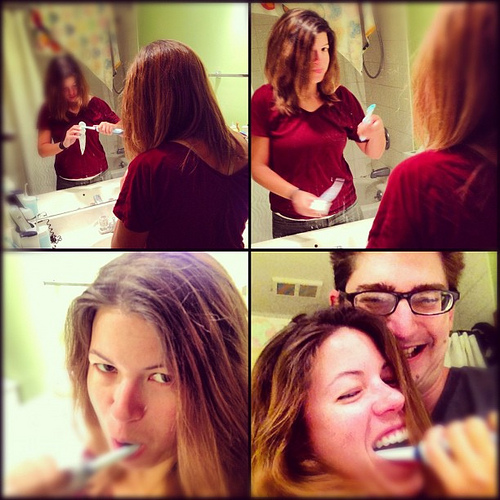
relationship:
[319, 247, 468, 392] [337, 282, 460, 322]
man with glasses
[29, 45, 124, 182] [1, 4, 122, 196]
reflection in mirror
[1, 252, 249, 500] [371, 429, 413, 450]
girl brushing teeth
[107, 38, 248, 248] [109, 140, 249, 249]
girl wearing shirt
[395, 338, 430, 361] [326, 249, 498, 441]
smile on man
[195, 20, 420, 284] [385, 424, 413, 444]
person brushing teeth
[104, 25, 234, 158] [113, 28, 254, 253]
brown hair on a woman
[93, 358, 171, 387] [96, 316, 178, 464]
eyes on a face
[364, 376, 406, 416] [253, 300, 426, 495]
nose on a face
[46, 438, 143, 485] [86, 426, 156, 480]
toothbrush inside mouth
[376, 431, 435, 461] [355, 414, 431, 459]
toothbrush in mouth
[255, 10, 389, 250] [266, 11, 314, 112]
girl on hair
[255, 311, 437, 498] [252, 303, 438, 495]
girl has hair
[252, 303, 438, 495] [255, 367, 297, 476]
hair has blonde streaks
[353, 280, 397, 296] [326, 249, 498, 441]
eyebrow on face of man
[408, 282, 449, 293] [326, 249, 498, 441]
eyebrow on face of man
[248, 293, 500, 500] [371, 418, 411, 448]
person brush teeth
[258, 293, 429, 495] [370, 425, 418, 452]
person brush teeth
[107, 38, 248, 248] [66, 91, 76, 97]
girl brush teeth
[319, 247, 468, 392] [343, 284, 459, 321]
man wearing glasses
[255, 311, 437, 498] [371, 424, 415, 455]
girl brushing teeth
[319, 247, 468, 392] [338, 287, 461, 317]
man has glasses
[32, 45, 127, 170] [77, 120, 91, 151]
girl putting toothpaste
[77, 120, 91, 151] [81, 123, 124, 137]
toothpaste on toothbrush